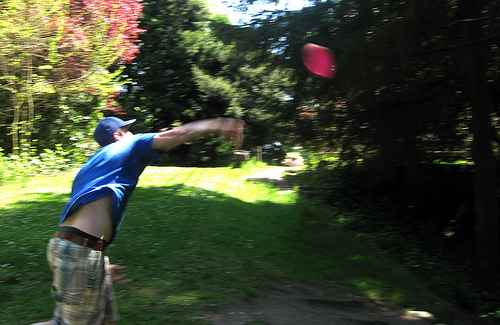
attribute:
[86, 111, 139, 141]
cap — blue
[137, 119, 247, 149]
arm — extended, blurry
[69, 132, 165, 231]
shirt — blue, plain, lifted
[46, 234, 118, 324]
shorts — plaid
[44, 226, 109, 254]
belt — brown, leather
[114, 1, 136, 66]
leaves — red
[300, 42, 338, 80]
frisbee — red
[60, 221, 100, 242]
underwear — black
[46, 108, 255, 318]
man — throwing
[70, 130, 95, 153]
flowers — white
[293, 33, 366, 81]
football — in air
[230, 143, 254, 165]
postal box — wooden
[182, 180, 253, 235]
grass — green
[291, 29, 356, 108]
water balloon — red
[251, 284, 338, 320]
dirt — brown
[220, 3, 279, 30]
sky — blue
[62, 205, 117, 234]
back — exposed